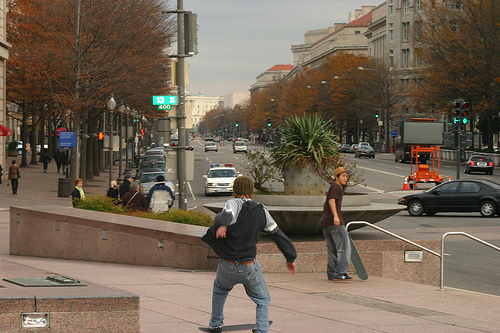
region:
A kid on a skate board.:
[185, 169, 287, 332]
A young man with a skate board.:
[311, 166, 379, 289]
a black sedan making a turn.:
[389, 172, 499, 224]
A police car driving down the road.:
[198, 155, 257, 202]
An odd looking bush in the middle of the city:
[259, 107, 357, 204]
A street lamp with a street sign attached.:
[150, 1, 207, 211]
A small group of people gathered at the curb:
[65, 167, 184, 237]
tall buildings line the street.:
[157, 2, 471, 158]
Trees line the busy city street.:
[181, 41, 399, 153]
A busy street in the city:
[177, 119, 498, 276]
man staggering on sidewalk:
[197, 174, 299, 331]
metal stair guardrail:
[438, 230, 498, 292]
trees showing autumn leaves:
[1, 2, 497, 182]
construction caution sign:
[400, 114, 455, 191]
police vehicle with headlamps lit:
[201, 161, 243, 198]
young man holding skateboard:
[316, 165, 368, 282]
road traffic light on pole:
[158, 1, 200, 211]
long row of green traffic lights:
[211, 111, 473, 136]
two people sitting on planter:
[119, 171, 178, 213]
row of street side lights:
[103, 89, 148, 197]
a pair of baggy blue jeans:
[212, 261, 269, 331]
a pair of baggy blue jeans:
[321, 220, 355, 282]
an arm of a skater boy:
[212, 200, 238, 237]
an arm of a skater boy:
[256, 203, 298, 274]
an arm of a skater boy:
[327, 188, 345, 225]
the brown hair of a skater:
[234, 175, 253, 197]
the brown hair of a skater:
[333, 169, 343, 179]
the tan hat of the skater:
[333, 167, 347, 176]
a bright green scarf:
[72, 185, 87, 201]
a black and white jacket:
[145, 185, 173, 213]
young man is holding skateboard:
[315, 163, 369, 282]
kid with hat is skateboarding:
[200, 175, 300, 330]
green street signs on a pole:
[149, 90, 181, 115]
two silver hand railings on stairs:
[342, 218, 499, 295]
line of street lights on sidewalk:
[103, 93, 144, 200]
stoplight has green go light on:
[449, 96, 470, 185]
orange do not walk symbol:
[96, 130, 106, 141]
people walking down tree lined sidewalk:
[0, 110, 131, 210]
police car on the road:
[201, 163, 245, 196]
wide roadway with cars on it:
[162, 113, 489, 201]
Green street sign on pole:
[146, 84, 191, 115]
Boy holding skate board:
[317, 158, 374, 291]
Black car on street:
[396, 170, 497, 225]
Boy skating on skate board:
[197, 162, 304, 332]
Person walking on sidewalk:
[1, 151, 31, 203]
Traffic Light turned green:
[447, 95, 474, 130]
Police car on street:
[199, 155, 247, 203]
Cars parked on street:
[132, 135, 179, 213]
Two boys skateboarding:
[195, 155, 376, 331]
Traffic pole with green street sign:
[147, 6, 209, 225]